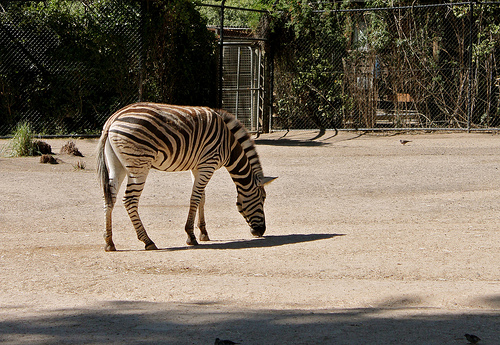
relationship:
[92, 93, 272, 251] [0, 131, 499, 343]
zebra on sand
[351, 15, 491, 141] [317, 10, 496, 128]
vines behind fence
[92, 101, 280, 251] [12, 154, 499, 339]
zebra standing on gravel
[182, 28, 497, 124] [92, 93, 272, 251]
fence around zebra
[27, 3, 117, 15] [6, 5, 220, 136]
bush behind fence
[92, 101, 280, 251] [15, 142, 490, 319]
zebra sniffing ground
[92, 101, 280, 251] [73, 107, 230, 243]
zebra has body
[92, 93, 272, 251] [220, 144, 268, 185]
zebra on neck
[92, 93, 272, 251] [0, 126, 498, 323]
zebra standing on ground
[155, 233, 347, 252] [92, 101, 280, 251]
shadow of a zebra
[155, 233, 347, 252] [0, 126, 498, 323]
shadow on ground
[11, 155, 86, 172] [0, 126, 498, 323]
dirt on ground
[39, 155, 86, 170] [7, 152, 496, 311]
dirt on ground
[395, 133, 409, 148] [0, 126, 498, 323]
bird on ground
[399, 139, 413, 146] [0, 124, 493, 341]
bird on ground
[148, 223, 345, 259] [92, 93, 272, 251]
shadow of zebra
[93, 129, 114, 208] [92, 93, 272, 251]
tail on zebra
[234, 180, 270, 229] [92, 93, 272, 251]
head on zebra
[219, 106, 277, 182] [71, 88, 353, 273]
mane on zebra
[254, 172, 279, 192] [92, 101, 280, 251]
ear on zebra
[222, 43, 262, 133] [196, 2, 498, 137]
gate to fence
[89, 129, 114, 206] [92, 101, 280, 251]
tail of a zebra